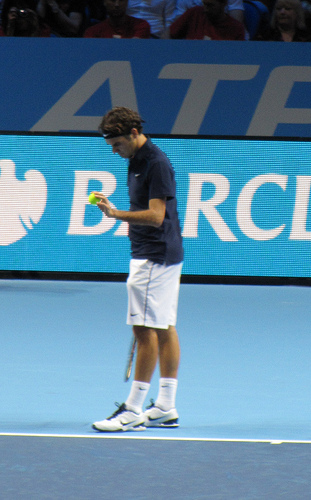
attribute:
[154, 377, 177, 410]
sock — white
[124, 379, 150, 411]
sock — white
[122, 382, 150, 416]
sock — Nike, athletic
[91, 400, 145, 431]
shoe — white, black, nike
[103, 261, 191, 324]
shorts — black, white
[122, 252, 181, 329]
short pants — white 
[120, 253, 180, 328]
shorts — white 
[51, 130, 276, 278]
sign — sponsor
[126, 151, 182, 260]
blue shirt — Dark blue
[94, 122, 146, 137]
headband — black, white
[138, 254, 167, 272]
pocket — pants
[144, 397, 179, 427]
shoe — nike, white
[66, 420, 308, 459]
lines — white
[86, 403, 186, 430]
shoes — white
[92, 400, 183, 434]
shoes — Nike 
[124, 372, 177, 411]
nike socks — white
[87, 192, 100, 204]
tennis ball — neon green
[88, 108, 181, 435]
player — serve-readying, tennis, professional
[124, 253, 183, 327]
tennis shorts — white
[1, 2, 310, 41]
crowd — tennis-watching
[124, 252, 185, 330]
shorts — white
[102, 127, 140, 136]
headband — dark blue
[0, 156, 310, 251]
logo — white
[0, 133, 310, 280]
wall — blue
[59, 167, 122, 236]
ball — yellow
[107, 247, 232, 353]
shorts — white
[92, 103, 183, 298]
player — tennis player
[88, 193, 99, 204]
tennis ball — bright, green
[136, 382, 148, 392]
logo — nike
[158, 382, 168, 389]
logo — nike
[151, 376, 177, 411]
sock — Nike, athletic, white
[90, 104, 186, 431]
tennis player — professional, male